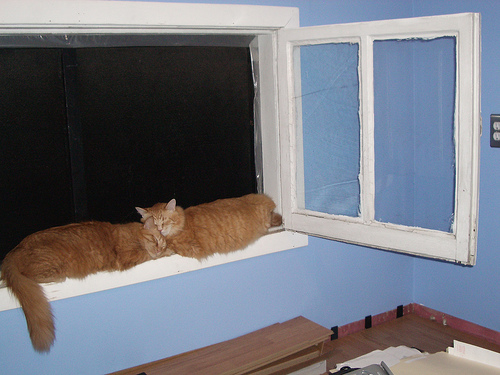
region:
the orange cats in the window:
[5, 182, 280, 349]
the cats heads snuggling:
[129, 197, 191, 260]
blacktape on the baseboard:
[325, 302, 412, 342]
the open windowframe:
[278, 6, 483, 267]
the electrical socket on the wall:
[488, 110, 498, 151]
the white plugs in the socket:
[489, 109, 498, 151]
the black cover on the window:
[0, 31, 264, 193]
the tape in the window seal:
[0, 28, 257, 55]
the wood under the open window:
[138, 303, 338, 374]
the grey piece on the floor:
[329, 355, 400, 374]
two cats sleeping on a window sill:
[1, 193, 283, 354]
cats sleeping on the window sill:
[2, 193, 283, 355]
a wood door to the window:
[280, 11, 480, 267]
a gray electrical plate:
[486, 112, 496, 147]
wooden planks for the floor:
[100, 313, 336, 373]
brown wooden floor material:
[108, 314, 335, 374]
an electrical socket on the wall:
[487, 113, 498, 148]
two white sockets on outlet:
[491, 121, 498, 138]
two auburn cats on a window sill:
[0, 193, 282, 353]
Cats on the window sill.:
[1, 193, 291, 355]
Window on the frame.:
[284, 19, 477, 268]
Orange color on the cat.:
[139, 180, 282, 262]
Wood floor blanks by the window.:
[81, 315, 333, 374]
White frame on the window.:
[279, 9, 479, 271]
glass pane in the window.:
[362, 32, 464, 242]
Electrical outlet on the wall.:
[485, 109, 498, 151]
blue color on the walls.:
[0, 3, 498, 374]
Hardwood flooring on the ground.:
[327, 308, 494, 374]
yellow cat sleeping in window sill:
[136, 192, 281, 260]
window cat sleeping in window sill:
[1, 214, 176, 351]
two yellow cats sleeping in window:
[0, 193, 282, 353]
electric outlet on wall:
[489, 114, 499, 146]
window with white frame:
[274, 12, 479, 267]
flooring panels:
[106, 315, 333, 374]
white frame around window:
[0, 0, 307, 312]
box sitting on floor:
[328, 339, 499, 374]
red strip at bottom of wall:
[324, 304, 499, 346]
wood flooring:
[323, 311, 498, 374]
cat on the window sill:
[6, 215, 166, 351]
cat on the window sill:
[137, 192, 285, 257]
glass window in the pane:
[296, 39, 360, 214]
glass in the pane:
[371, 35, 459, 229]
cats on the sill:
[3, 188, 283, 353]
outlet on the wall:
[489, 117, 499, 146]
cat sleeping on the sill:
[1, 222, 164, 355]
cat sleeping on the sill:
[135, 191, 285, 255]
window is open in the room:
[281, 11, 483, 264]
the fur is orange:
[199, 216, 238, 243]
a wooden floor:
[393, 320, 424, 342]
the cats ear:
[163, 196, 180, 216]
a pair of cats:
[3, 188, 288, 365]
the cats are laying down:
[5, 171, 288, 368]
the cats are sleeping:
[9, 175, 300, 365]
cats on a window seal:
[5, 185, 291, 354]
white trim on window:
[274, 14, 479, 268]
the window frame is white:
[0, 8, 312, 315]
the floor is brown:
[345, 300, 442, 362]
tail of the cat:
[11, 273, 68, 360]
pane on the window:
[280, 38, 360, 220]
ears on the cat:
[136, 191, 186, 227]